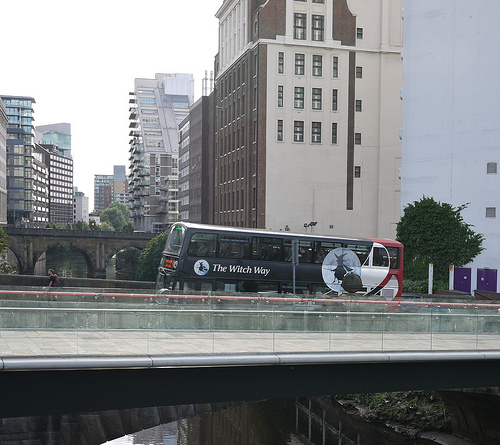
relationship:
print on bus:
[213, 263, 271, 277] [144, 222, 484, 318]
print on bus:
[211, 264, 271, 276] [151, 221, 404, 318]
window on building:
[296, 50, 304, 79] [249, 0, 399, 240]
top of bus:
[176, 219, 403, 242] [151, 221, 404, 318]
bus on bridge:
[146, 205, 416, 328] [12, 279, 496, 394]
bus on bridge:
[151, 221, 404, 318] [0, 283, 496, 420]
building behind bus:
[207, 2, 417, 254] [145, 215, 411, 320]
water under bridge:
[192, 367, 386, 432] [0, 283, 496, 420]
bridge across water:
[0, 227, 157, 277] [147, 430, 252, 440]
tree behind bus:
[397, 198, 468, 296] [151, 221, 404, 318]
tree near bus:
[394, 193, 486, 296] [151, 221, 404, 318]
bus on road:
[151, 221, 404, 318] [12, 309, 282, 354]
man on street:
[48, 265, 59, 289] [0, 290, 499, 331]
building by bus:
[213, 0, 402, 241] [159, 209, 423, 322]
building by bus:
[400, 0, 499, 297] [159, 209, 423, 322]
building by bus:
[178, 110, 192, 222] [159, 209, 423, 322]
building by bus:
[159, 174, 180, 229] [159, 209, 423, 322]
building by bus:
[189, 52, 218, 223] [159, 209, 423, 322]